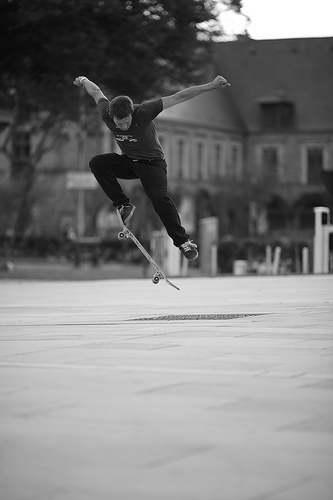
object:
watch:
[78, 75, 91, 84]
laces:
[179, 237, 198, 255]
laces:
[117, 201, 126, 214]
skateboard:
[116, 212, 178, 292]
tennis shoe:
[177, 240, 200, 263]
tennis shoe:
[119, 199, 136, 227]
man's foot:
[114, 198, 134, 224]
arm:
[132, 80, 212, 126]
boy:
[71, 75, 231, 263]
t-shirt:
[96, 95, 165, 163]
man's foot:
[176, 238, 200, 262]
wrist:
[79, 77, 88, 86]